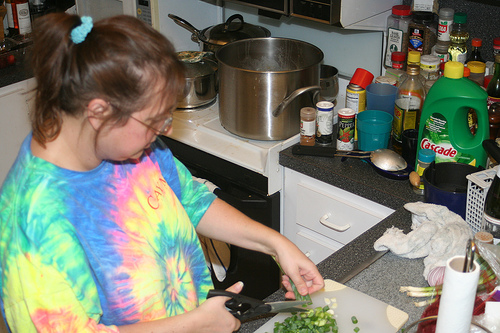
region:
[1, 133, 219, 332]
shirt is tie dye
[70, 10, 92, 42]
scrunchie holds hair in place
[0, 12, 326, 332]
woman holds scissors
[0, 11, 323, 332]
woman prepares food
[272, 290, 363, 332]
vegetables are on cutting board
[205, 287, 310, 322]
scissors cut food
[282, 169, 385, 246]
drawer is closed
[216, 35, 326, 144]
pot sits on stove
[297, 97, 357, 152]
spices sit on counter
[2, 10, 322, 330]
woman cutting vegetables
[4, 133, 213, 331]
tie dye shirt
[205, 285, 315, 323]
black handled scissors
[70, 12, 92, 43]
light blue hair scrunchie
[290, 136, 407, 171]
large ladle with black handle on counter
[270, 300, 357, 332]
pile of cut green onions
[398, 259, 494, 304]
whole green onions on the counter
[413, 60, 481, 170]
large green bottle of Cascade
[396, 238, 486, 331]
silver wire paper towel holder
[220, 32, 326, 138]
a large gray pot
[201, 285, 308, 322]
black and silver scissors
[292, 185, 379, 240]
part of a white drawer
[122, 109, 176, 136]
a woman's eyeglasses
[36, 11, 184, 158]
a woman's brown hair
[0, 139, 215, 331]
a woman's colorful shirt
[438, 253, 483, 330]
a roll of paper towels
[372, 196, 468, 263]
a white rag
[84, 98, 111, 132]
the ear of a woman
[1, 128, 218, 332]
Lady wears tie-dyed top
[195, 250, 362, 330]
Lady is chopping up green onions using scissors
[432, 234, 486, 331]
Roll of paper towels is almost exhausted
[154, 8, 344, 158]
Various pots on stovetop waiting for ingredients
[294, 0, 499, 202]
Kitchen supplies and food items share countertop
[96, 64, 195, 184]
Lady wears glasses to compensate for eye weakness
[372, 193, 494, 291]
A dishrag lays messily on the counter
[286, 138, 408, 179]
A large metal spoon for stirring the pot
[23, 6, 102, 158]
A so-called "scrunchy" makes this lady's pony tail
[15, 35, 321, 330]
girl cutting vegetables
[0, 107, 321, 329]
woman is wearing a tiedye shirt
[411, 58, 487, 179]
A large container of diswasher detergent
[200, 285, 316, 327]
woman using scissors to cut vegetables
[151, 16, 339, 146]
pots on the stove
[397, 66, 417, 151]
a bottle of olive oil on the counter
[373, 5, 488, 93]
a variety of spices and condiments on the right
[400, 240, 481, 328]
paper towel holder in front of cutting board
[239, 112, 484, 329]
grey countertops